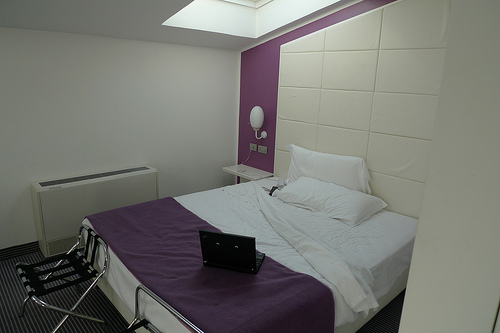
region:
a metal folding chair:
[14, 223, 109, 331]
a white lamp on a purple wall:
[249, 105, 267, 140]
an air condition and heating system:
[32, 162, 157, 257]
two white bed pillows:
[275, 144, 389, 224]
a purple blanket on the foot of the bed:
[85, 196, 335, 331]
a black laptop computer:
[198, 228, 266, 275]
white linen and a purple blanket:
[80, 176, 417, 329]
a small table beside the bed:
[219, 163, 273, 180]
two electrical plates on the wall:
[242, 142, 274, 154]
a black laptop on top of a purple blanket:
[152, 228, 312, 291]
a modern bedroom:
[3, 2, 493, 312]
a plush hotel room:
[1, 0, 491, 312]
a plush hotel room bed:
[15, 10, 496, 310]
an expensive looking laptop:
[180, 221, 280, 286]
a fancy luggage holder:
[5, 215, 106, 330]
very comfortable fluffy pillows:
[265, 126, 400, 241]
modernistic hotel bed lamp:
[241, 95, 281, 160]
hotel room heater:
[22, 160, 172, 271]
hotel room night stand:
[215, 145, 280, 210]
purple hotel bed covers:
[71, 195, 346, 315]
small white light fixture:
[241, 98, 275, 143]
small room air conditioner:
[21, 146, 168, 261]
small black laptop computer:
[183, 212, 275, 284]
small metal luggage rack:
[11, 212, 118, 331]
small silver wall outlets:
[230, 138, 275, 162]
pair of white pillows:
[272, 131, 394, 241]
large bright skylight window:
[155, 0, 371, 43]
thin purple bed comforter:
[75, 187, 347, 332]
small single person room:
[3, 0, 497, 330]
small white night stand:
[219, 138, 277, 188]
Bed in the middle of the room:
[56, 179, 433, 324]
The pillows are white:
[251, 138, 412, 228]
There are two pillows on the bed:
[261, 141, 395, 228]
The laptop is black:
[176, 203, 287, 288]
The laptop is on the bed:
[188, 213, 280, 289]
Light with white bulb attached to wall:
[240, 97, 284, 152]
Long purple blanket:
[86, 191, 341, 327]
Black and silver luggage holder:
[10, 218, 132, 328]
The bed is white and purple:
[62, 201, 440, 322]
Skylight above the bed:
[131, 1, 345, 53]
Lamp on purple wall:
[249, 102, 266, 147]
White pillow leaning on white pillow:
[269, 168, 394, 231]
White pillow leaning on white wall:
[284, 140, 384, 200]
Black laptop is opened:
[192, 225, 267, 278]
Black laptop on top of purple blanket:
[195, 229, 269, 275]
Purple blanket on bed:
[83, 190, 339, 331]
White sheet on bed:
[78, 175, 415, 332]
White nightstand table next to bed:
[218, 159, 273, 184]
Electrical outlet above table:
[245, 140, 258, 155]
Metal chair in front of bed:
[14, 220, 116, 332]